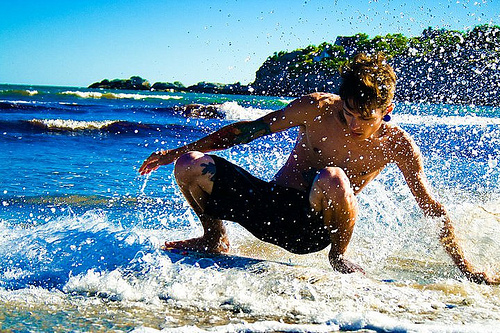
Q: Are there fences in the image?
A: No, there are no fences.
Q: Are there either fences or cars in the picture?
A: No, there are no fences or cars.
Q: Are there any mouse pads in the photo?
A: No, there are no mouse pads.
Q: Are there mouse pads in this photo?
A: No, there are no mouse pads.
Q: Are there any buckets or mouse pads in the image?
A: No, there are no mouse pads or buckets.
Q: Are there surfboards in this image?
A: No, there are no surfboards.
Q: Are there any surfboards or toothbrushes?
A: No, there are no surfboards or toothbrushes.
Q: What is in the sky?
A: The clouds are in the sky.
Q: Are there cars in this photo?
A: No, there are no cars.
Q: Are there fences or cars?
A: No, there are no cars or fences.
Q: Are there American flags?
A: No, there are no American flags.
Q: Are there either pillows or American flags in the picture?
A: No, there are no American flags or pillows.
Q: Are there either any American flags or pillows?
A: No, there are no American flags or pillows.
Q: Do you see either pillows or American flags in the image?
A: No, there are no American flags or pillows.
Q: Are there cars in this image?
A: No, there are no cars.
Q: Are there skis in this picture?
A: No, there are no skis.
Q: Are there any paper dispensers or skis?
A: No, there are no skis or paper dispensers.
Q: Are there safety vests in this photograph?
A: No, there are no safety vests.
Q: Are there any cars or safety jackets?
A: No, there are no safety jackets or cars.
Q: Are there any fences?
A: No, there are no fences.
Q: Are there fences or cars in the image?
A: No, there are no fences or cars.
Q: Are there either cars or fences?
A: No, there are no fences or cars.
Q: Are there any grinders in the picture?
A: No, there are no grinders.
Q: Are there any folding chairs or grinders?
A: No, there are no grinders or folding chairs.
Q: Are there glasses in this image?
A: No, there are no glasses.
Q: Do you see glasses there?
A: No, there are no glasses.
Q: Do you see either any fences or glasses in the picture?
A: No, there are no glasses or fences.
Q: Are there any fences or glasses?
A: No, there are no glasses or fences.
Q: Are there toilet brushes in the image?
A: No, there are no toilet brushes.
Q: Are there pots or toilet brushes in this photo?
A: No, there are no toilet brushes or pots.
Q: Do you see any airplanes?
A: No, there are no airplanes.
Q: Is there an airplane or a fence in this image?
A: No, there are no airplanes or fences.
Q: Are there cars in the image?
A: No, there are no cars.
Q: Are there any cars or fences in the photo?
A: No, there are no cars or fences.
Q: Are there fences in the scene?
A: No, there are no fences.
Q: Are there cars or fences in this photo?
A: No, there are no fences or cars.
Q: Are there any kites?
A: No, there are no kites.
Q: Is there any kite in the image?
A: No, there are no kites.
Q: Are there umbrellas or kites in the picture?
A: No, there are no kites or umbrellas.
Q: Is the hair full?
A: Yes, the hair is full.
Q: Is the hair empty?
A: No, the hair is full.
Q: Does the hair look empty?
A: No, the hair is full.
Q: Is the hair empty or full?
A: The hair is full.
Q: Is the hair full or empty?
A: The hair is full.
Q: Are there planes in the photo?
A: No, there are no planes.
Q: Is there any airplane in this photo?
A: No, there are no airplanes.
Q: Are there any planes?
A: No, there are no planes.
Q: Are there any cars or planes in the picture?
A: No, there are no planes or cars.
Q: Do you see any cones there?
A: No, there are no cones.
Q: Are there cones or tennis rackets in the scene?
A: No, there are no cones or tennis rackets.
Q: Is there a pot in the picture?
A: No, there are no pots.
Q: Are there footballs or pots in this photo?
A: No, there are no pots or footballs.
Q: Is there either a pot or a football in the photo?
A: No, there are no pots or footballs.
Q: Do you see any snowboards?
A: No, there are no snowboards.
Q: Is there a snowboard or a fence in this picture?
A: No, there are no snowboards or fences.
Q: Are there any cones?
A: No, there are no cones.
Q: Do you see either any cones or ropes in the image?
A: No, there are no cones or ropes.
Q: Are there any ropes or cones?
A: No, there are no cones or ropes.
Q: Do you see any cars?
A: No, there are no cars.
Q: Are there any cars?
A: No, there are no cars.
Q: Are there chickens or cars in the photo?
A: No, there are no cars or chickens.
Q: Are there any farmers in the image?
A: No, there are no farmers.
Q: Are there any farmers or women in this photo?
A: No, there are no farmers or women.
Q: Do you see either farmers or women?
A: No, there are no farmers or women.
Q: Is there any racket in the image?
A: No, there are no rackets.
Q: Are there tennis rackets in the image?
A: No, there are no tennis rackets.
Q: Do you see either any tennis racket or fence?
A: No, there are no rackets or fences.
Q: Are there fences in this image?
A: No, there are no fences.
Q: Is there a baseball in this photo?
A: No, there are no baseballs.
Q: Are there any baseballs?
A: No, there are no baseballs.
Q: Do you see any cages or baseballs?
A: No, there are no baseballs or cages.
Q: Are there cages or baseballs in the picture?
A: No, there are no baseballs or cages.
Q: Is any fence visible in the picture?
A: No, there are no fences.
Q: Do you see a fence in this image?
A: No, there are no fences.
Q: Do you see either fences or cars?
A: No, there are no fences or cars.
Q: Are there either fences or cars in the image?
A: No, there are no fences or cars.